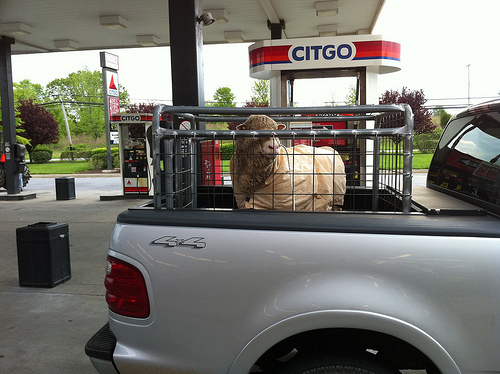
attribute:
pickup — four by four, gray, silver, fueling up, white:
[82, 99, 499, 373]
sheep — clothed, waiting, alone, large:
[227, 112, 348, 212]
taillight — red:
[103, 253, 150, 318]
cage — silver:
[151, 104, 414, 214]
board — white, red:
[103, 53, 121, 70]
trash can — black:
[14, 220, 74, 288]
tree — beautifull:
[15, 99, 57, 168]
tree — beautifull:
[380, 90, 438, 164]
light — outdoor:
[221, 29, 252, 45]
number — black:
[178, 235, 213, 252]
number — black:
[152, 234, 177, 248]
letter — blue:
[338, 44, 353, 61]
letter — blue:
[321, 44, 336, 61]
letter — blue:
[311, 44, 323, 61]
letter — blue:
[303, 45, 311, 60]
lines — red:
[353, 40, 403, 64]